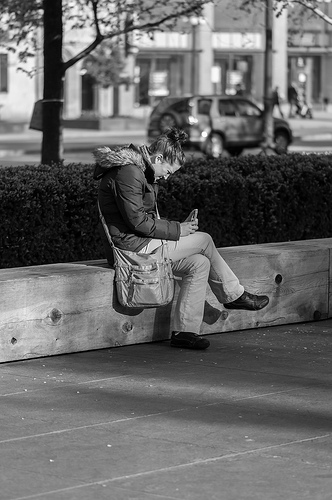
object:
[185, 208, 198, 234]
plate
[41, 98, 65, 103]
line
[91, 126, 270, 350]
lady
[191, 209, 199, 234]
cell phone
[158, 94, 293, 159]
car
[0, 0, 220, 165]
tree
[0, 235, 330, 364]
plank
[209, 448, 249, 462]
part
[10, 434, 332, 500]
line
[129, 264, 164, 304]
pocket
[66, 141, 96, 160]
street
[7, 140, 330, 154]
road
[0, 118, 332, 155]
tarmac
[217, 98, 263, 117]
window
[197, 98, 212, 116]
window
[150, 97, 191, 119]
window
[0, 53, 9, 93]
window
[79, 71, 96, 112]
window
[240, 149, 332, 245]
hedge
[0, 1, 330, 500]
photo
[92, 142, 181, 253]
jacket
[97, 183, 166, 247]
strap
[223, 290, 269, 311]
shoe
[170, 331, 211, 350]
shoe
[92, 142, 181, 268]
coat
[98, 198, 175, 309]
bag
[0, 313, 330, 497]
floor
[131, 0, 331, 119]
building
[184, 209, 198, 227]
cake